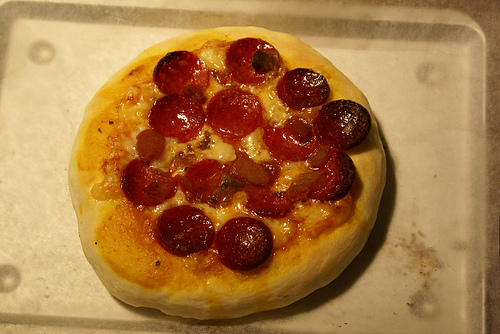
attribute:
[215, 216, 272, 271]
pepperoni — red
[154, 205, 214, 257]
pepperoni — red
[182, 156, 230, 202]
pepperoni — red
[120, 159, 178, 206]
pepperoni — red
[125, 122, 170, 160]
onion — browned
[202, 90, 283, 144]
pepperoni — red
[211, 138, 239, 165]
cheese — yellow, pretty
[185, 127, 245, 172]
cheese — melted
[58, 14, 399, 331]
pizza — prepared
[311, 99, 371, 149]
pepperoni — red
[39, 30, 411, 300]
pizza — prepared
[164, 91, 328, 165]
pepperoni — red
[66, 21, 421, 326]
pizza crust — golden brown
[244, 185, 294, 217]
pepperoni — red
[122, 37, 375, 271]
pepperoni — burnt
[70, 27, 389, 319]
pizza — prepared, pepperoni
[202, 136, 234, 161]
cheese — melted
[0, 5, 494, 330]
pan — baking, metal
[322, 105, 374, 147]
pepperoni — red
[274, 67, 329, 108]
pepperoni — red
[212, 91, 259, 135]
pepperoni — red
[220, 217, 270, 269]
pepperoni — red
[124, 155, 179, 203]
pepperoni — red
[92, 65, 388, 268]
pizza — prepared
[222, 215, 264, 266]
pepperoni — red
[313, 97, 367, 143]
pepperoni — extra crispy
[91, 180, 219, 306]
crust — tan, light